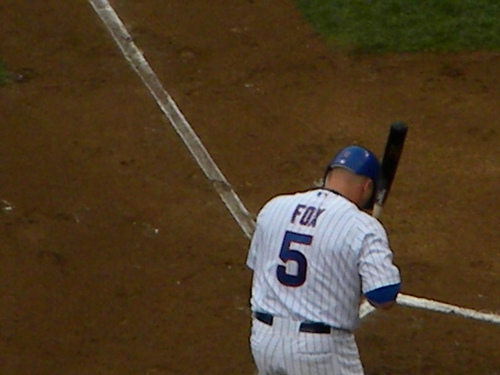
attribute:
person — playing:
[234, 137, 409, 373]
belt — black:
[255, 304, 334, 333]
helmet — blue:
[326, 140, 381, 184]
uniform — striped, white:
[244, 188, 399, 374]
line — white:
[89, 0, 256, 235]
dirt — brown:
[2, 0, 497, 370]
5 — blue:
[277, 226, 316, 288]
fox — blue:
[286, 199, 329, 229]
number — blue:
[276, 227, 316, 288]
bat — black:
[365, 116, 411, 216]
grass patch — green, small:
[295, 3, 499, 58]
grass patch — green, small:
[302, 0, 499, 62]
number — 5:
[270, 224, 319, 287]